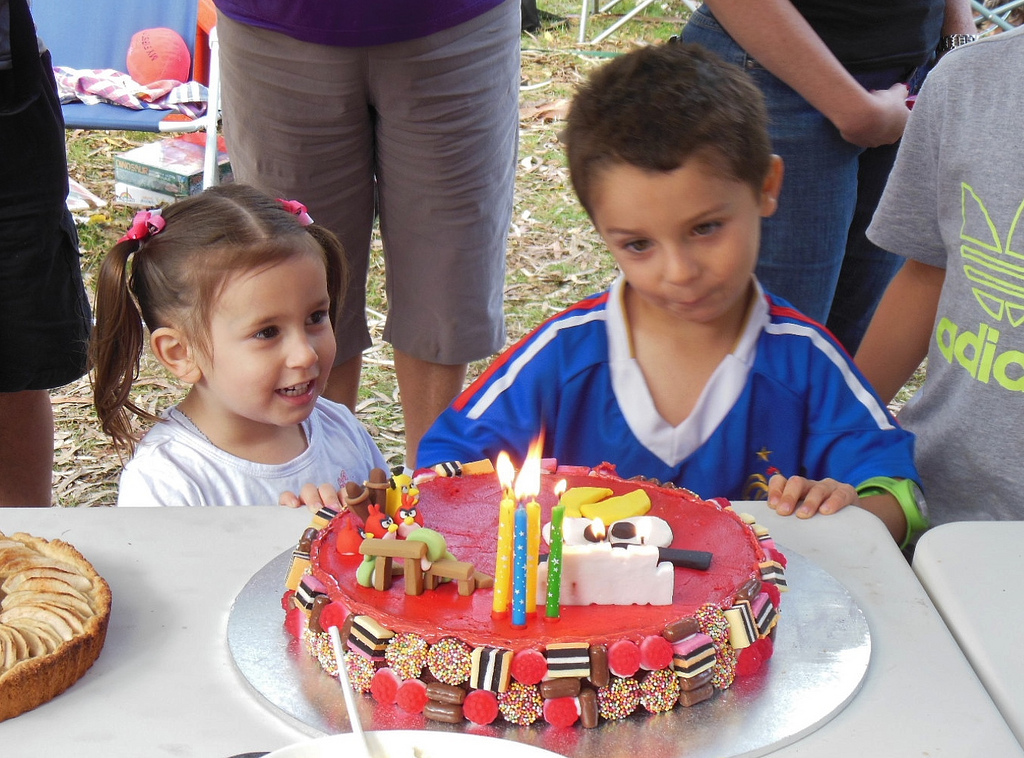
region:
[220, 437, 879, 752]
colorful cake on a silver tray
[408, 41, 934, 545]
little boy wearing a blue, white, and red top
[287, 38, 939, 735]
boy looking at the cake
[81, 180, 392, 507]
little girl wearing white top and pigtails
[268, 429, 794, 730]
candles on cake are lit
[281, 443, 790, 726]
edge of cake is covered in candy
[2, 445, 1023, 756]
cake on top of white table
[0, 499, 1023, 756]
apple tart on white table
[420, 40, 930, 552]
little boy has brown hair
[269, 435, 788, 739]
cake is round and red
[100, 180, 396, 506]
Girl with ribbons in hair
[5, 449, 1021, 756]
Cake on top of table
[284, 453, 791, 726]
Candy on the cake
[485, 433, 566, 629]
Flames on the candle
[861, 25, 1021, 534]
A gray adidas shirt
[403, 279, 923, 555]
Blue shirt has stripes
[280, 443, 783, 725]
Angry birds on top of cake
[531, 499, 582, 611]
candle in the cake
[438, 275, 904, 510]
boy wearing a blue shirt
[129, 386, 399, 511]
girl wearing a white shirt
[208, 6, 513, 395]
man wearing grey shorts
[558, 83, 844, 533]
a person standing outside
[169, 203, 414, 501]
a person standing outside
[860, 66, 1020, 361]
a person standing outside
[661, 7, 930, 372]
a person standing outside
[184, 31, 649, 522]
a person standing outside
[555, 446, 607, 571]
a candle on the cake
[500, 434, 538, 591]
a candle on the cake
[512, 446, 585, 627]
a candle on the cake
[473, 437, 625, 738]
a candle on the cake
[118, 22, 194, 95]
Pink balloon on the floor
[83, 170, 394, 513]
Little girl with pigtails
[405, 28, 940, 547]
Little boy looking at a birthday cake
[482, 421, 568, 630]
Four candles on a birthday cake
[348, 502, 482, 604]
Animals on a birthday cake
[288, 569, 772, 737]
Candy edges on a birthday cake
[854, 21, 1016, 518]
Onlooker with gray Adidas shirt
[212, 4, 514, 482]
Onlooker with gray capris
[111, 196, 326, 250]
Pink barrettes in little girl's hair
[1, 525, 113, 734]
Pastry on table, next to birthday cake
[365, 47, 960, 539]
boy in front of birthday cake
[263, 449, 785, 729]
red designed birthday cake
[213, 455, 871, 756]
silver metal circular tray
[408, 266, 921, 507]
blue soccer jersey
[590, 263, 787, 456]
white collar on jersey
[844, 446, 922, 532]
lime green watch on wrist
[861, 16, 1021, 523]
short sleeve gray shirt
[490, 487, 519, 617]
yellow birthday cake candle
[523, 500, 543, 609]
yellow birthday cake candle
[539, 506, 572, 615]
green birthday cake candle